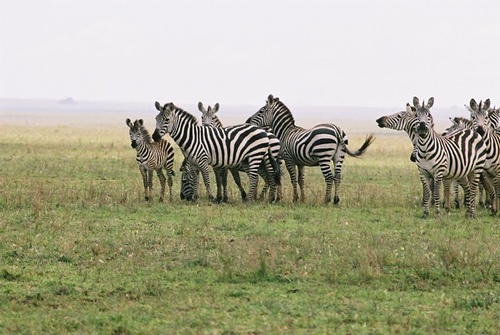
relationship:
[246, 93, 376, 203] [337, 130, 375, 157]
zebra has tail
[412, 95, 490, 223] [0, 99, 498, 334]
zebra stand on grass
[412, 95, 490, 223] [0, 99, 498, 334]
zebra stands on grass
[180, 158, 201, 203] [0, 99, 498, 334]
zebra eating grass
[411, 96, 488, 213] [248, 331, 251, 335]
zebra faces away camera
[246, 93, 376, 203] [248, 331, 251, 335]
zebra faces away camera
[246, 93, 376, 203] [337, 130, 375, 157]
zebra swishes tail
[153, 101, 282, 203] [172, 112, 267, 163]
zebra shows stripes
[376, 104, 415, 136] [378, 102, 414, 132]
zebra lifts head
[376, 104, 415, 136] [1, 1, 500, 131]
zebra sniffs air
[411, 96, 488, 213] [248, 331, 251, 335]
zebra stares away camera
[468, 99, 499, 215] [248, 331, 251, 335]
zebra stares away camera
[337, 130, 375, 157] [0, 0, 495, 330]
tail swishes in the air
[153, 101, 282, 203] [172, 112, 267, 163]
zebra has stripes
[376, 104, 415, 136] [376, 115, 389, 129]
zebra has pointed nose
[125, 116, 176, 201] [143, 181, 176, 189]
zebra has knobby knees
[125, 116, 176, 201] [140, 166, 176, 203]
zebra has skinny hind legs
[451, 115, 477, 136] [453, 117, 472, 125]
zebra has mane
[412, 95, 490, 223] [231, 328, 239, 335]
zebra looking photographer